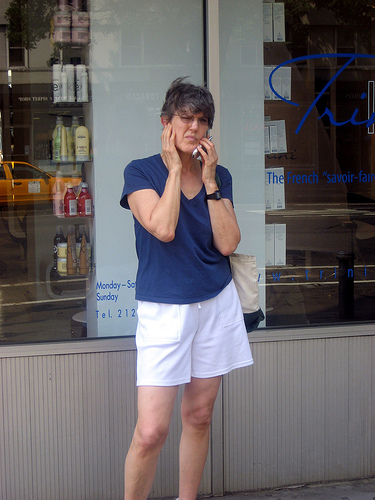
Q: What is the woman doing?
A: Talking on a cell phone.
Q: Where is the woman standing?
A: In front of a store.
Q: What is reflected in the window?
A: A car.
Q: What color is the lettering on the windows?
A: Blue.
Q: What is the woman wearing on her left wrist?
A: A watch.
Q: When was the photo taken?
A: Daytime.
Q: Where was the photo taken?
A: In front of a storefront.